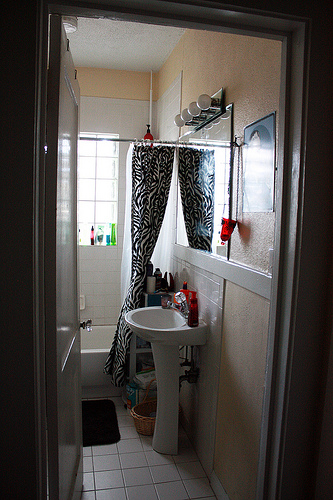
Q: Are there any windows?
A: Yes, there is a window.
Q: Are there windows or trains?
A: Yes, there is a window.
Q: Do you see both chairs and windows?
A: No, there is a window but no chairs.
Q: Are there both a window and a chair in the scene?
A: No, there is a window but no chairs.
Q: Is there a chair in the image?
A: No, there are no chairs.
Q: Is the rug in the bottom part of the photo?
A: Yes, the rug is in the bottom of the image.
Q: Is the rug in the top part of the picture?
A: No, the rug is in the bottom of the image.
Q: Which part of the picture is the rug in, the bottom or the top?
A: The rug is in the bottom of the image.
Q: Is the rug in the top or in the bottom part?
A: The rug is in the bottom of the image.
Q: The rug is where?
A: The rug is on the floor.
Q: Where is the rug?
A: The rug is on the floor.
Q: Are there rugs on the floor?
A: Yes, there is a rug on the floor.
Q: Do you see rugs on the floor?
A: Yes, there is a rug on the floor.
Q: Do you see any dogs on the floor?
A: No, there is a rug on the floor.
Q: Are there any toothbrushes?
A: No, there are no toothbrushes.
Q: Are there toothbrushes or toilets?
A: No, there are no toothbrushes or toilets.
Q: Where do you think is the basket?
A: The basket is on the floor.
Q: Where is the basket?
A: The basket is on the floor.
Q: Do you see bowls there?
A: No, there are no bowls.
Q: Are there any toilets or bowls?
A: No, there are no bowls or toilets.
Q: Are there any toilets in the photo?
A: No, there are no toilets.